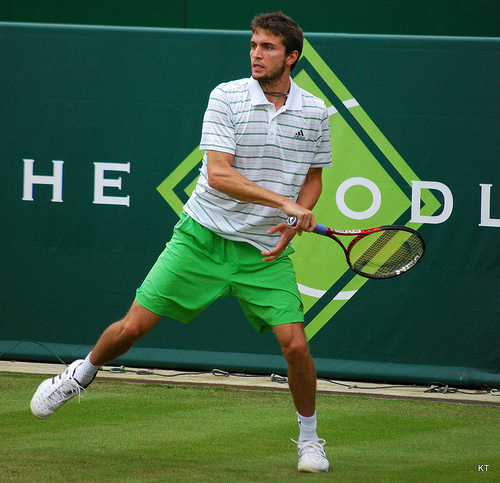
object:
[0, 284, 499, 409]
grass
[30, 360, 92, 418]
shoe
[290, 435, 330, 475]
shoe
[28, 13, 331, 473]
man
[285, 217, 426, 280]
racket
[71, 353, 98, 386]
sock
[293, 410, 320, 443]
sock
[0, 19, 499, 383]
wall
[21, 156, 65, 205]
letter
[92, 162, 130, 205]
letter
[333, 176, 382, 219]
letter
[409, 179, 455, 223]
letter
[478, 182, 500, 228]
letter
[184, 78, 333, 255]
shirt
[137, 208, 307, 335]
shorts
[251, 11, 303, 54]
hair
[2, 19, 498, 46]
edge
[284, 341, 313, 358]
knee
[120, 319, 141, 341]
knee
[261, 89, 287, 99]
necklace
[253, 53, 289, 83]
beard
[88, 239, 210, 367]
leg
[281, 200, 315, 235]
hand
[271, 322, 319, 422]
leg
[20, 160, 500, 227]
word